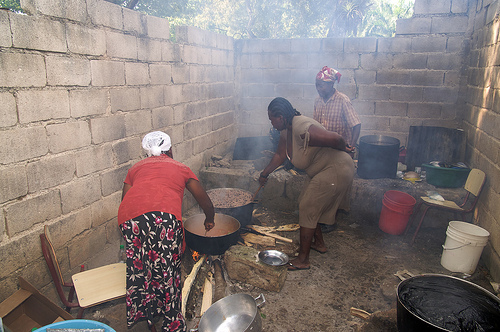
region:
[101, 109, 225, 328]
woman bending over a pot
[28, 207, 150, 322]
wooden chair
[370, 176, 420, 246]
red plastic bucket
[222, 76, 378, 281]
woman wearing a tan outfit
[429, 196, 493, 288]
white plastic bucket with a handle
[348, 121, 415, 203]
tall metal stockpot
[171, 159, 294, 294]
two large pots over a fire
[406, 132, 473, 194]
green plastic tub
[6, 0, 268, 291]
stained cinder block wall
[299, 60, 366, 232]
person wearing a red and white head scarf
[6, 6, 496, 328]
people cooking in a building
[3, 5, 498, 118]
a building is open on top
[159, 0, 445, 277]
smoke coming from a wood stove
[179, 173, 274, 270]
two big pots on a wood stove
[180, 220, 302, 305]
logs are burned to make fire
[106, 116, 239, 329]
woman holds an utensil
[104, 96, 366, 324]
two woman moving pots with utensils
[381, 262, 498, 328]
a pot color black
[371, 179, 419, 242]
a red pail behind women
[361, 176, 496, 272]
a red and white pail in a kitchen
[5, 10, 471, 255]
The wall is made of grey cement blocks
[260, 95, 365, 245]
Women wearing a brown dress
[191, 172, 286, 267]
The pots are over a fire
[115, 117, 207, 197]
Person with a white hat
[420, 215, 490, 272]
The bin is white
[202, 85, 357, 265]
The women is stirring the contents of the pot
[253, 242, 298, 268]
Round silver pan on the ground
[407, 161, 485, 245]
The chair is brown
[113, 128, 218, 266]
The person is wearing a red shirt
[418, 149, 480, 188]
The bowl is large and green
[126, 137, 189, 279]
this is a lady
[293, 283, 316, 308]
this is the ground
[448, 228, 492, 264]
this is a jerican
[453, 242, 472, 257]
the jerican is whitre in color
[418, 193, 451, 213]
this is a chair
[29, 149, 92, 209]
this is the wall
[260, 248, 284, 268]
this is a plate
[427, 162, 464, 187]
this is the trough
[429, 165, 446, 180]
the trough is green in color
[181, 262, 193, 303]
this is a firewood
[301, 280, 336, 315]
this is the ground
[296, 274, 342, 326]
the ground is sandy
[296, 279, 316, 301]
the sand is brown in color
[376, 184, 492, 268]
these are two buckets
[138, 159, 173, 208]
the t-shirt is red in color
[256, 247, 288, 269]
the plate is metallic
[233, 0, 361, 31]
this is a tree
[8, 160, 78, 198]
this is a wall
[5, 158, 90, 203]
the wall is made of stone